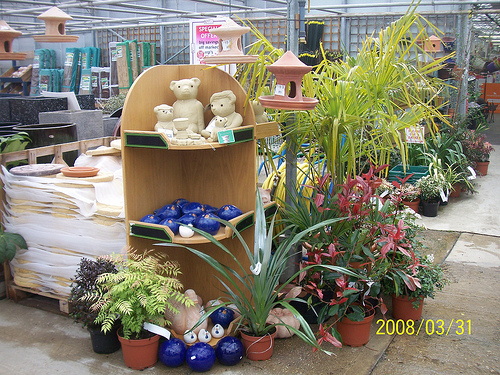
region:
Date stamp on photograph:
[372, 316, 474, 337]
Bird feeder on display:
[33, 8, 81, 43]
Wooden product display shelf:
[118, 62, 268, 352]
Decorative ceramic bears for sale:
[148, 75, 243, 152]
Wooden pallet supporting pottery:
[5, 284, 85, 316]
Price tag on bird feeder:
[272, 80, 285, 97]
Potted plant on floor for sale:
[89, 247, 194, 369]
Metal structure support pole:
[283, 2, 301, 292]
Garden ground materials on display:
[28, 39, 155, 96]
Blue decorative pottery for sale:
[134, 198, 239, 233]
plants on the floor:
[255, 207, 445, 366]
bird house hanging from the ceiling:
[17, 2, 83, 58]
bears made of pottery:
[119, 65, 255, 154]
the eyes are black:
[169, 76, 202, 96]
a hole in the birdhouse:
[48, 20, 73, 39]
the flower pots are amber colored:
[306, 272, 428, 369]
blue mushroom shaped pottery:
[136, 171, 239, 241]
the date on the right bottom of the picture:
[323, 291, 478, 353]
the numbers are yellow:
[353, 309, 480, 358]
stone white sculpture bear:
[154, 66, 248, 153]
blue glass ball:
[160, 334, 242, 374]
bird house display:
[34, 5, 79, 55]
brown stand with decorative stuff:
[113, 49, 271, 327]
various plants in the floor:
[251, 23, 463, 328]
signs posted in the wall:
[184, 19, 236, 76]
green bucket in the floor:
[379, 159, 434, 185]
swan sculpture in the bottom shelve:
[169, 280, 209, 336]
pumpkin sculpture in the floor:
[256, 299, 300, 351]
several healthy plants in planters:
[243, 39, 455, 363]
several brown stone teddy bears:
[135, 76, 245, 146]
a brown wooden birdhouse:
[26, 5, 83, 49]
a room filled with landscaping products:
[2, 5, 474, 372]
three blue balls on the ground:
[160, 338, 244, 371]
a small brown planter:
[117, 329, 162, 369]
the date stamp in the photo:
[372, 317, 475, 343]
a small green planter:
[80, 323, 122, 356]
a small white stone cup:
[170, 117, 192, 142]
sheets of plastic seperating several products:
[5, 163, 130, 312]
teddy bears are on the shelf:
[161, 71, 220, 139]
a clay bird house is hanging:
[274, 46, 309, 110]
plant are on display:
[328, 189, 423, 323]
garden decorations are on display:
[136, 187, 245, 240]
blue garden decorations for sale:
[161, 198, 236, 228]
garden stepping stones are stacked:
[16, 159, 97, 246]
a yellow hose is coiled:
[255, 149, 310, 199]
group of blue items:
[126, 188, 243, 245]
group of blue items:
[135, 186, 252, 246]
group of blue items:
[129, 186, 254, 244]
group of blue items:
[136, 182, 258, 249]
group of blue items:
[130, 183, 248, 250]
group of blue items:
[132, 182, 252, 254]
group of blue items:
[135, 189, 254, 251]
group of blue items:
[124, 189, 248, 248]